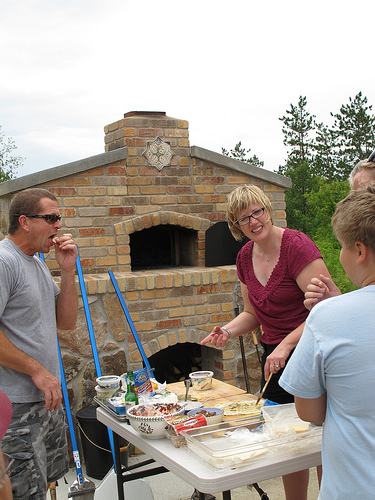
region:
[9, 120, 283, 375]
A pizza oven.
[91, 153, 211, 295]
It is made from bricks.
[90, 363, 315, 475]
A table full of food items.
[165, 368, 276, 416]
Two wooden cutting boards.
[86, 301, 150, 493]
A peel.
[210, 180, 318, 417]
The woman is preparing a pizza.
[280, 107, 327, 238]
Trees.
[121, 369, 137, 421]
A beer.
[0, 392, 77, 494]
The man is wearing camouflage pants.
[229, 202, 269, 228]
The woman is wearing glasses.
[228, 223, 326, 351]
short sleeve purple shirt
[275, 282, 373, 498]
short sleeve white tee shirt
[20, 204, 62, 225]
black sunglasses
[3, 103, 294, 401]
outdoor brick fireplace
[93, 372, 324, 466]
a table full of food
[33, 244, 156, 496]
three blue garden tools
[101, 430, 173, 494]
black table leg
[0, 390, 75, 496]
grey and black camouflage shorts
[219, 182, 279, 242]
she has short blonde hair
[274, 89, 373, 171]
two green pine trees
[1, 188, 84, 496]
the man is about to take a bite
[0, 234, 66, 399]
the man is wearing a grey shirt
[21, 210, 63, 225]
the man is wearing sunglasses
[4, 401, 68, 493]
the man is wearing shorts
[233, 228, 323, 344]
the woman is wearing a burgundy shirt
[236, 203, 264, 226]
the woman is wearing glasses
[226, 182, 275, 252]
the woman's hair is blonde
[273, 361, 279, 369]
the woman is wearing a wedding ring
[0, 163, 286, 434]
a brick oven is in the background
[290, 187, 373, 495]
the boy is wearing a blue shirt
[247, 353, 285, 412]
woman is holding a brush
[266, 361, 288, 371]
woman is wearing a ring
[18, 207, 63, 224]
man is wearing a sunglasses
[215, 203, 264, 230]
woman is wearing an eyeglasses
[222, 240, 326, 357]
the blouse is maroon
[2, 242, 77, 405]
the shirt is gray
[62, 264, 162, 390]
broom holders are blue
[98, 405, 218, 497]
the table is white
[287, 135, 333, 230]
the trees are green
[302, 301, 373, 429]
the shirt is light blue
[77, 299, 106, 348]
blue handle of broom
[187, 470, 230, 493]
edge of white table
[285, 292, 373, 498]
woman wearing blue shirt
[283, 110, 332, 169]
cluster of green trees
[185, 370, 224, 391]
small gray and yellow tub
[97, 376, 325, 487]
white table with ingredients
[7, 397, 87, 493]
gray cargo pants on man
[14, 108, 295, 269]
stone pit with marking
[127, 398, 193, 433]
white bowl with fresh fruit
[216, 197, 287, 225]
woman wearing black framed glasse